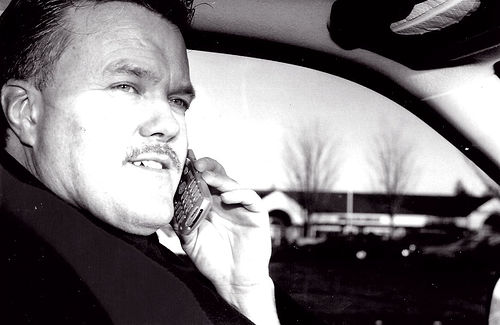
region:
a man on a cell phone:
[8, 3, 273, 319]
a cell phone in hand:
[175, 145, 275, 286]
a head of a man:
[2, 0, 192, 231]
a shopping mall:
[277, 185, 492, 250]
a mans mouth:
[117, 145, 178, 180]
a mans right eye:
[102, 65, 134, 100]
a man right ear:
[0, 72, 41, 152]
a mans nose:
[137, 86, 172, 137]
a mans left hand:
[197, 154, 285, 305]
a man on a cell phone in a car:
[12, 2, 474, 317]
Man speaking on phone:
[0, 1, 289, 321]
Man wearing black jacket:
[1, 0, 272, 324]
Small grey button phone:
[175, 145, 212, 243]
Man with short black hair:
[0, 0, 212, 82]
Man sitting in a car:
[0, 6, 499, 319]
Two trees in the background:
[283, 123, 418, 236]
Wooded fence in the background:
[271, 190, 470, 237]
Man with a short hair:
[122, 143, 185, 175]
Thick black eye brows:
[110, 59, 155, 78]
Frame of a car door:
[186, 24, 497, 185]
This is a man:
[32, 25, 196, 206]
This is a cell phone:
[173, 153, 237, 255]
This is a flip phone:
[189, 172, 211, 236]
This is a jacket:
[33, 230, 118, 294]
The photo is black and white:
[116, 168, 332, 298]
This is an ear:
[12, 68, 94, 255]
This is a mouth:
[71, 146, 243, 207]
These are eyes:
[90, 59, 248, 125]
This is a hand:
[183, 186, 273, 282]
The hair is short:
[0, 38, 62, 68]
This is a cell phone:
[138, 182, 230, 263]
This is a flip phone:
[155, 131, 203, 274]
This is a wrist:
[202, 281, 252, 311]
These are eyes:
[62, 46, 196, 118]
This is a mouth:
[69, 75, 219, 195]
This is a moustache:
[61, 88, 169, 160]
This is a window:
[158, 59, 393, 290]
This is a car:
[400, 238, 492, 300]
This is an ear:
[14, 101, 39, 168]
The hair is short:
[32, 21, 104, 143]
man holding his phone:
[12, 2, 248, 254]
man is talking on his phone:
[13, 25, 255, 245]